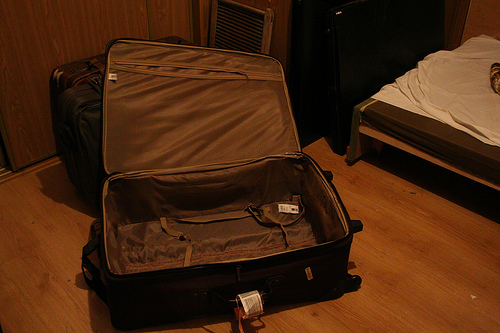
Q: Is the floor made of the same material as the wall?
A: Yes, both the floor and the wall are made of wood.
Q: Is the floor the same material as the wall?
A: Yes, both the floor and the wall are made of wood.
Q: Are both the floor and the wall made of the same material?
A: Yes, both the floor and the wall are made of wood.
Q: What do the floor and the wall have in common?
A: The material, both the floor and the wall are wooden.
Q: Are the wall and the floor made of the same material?
A: Yes, both the wall and the floor are made of wood.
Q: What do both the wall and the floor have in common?
A: The material, both the wall and the floor are wooden.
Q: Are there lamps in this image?
A: No, there are no lamps.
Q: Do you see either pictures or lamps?
A: No, there are no lamps or pictures.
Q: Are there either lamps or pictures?
A: No, there are no lamps or pictures.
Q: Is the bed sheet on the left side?
A: No, the bed sheet is on the right of the image.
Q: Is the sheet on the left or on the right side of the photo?
A: The sheet is on the right of the image.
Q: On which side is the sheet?
A: The sheet is on the right of the image.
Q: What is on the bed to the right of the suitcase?
A: The bed sheet is on the bed.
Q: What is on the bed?
A: The bed sheet is on the bed.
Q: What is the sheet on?
A: The sheet is on the bed.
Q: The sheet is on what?
A: The sheet is on the bed.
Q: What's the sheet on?
A: The sheet is on the bed.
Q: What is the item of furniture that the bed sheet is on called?
A: The piece of furniture is a bed.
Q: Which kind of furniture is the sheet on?
A: The bed sheet is on the bed.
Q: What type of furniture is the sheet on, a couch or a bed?
A: The sheet is on a bed.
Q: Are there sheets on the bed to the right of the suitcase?
A: Yes, there is a sheet on the bed.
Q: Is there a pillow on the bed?
A: No, there is a sheet on the bed.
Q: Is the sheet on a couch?
A: No, the sheet is on a bed.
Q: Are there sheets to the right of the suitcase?
A: Yes, there is a sheet to the right of the suitcase.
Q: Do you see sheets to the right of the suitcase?
A: Yes, there is a sheet to the right of the suitcase.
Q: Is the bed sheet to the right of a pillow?
A: No, the bed sheet is to the right of the suitcase.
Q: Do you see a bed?
A: Yes, there is a bed.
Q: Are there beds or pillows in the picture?
A: Yes, there is a bed.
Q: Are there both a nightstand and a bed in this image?
A: No, there is a bed but no nightstands.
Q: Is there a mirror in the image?
A: No, there are no mirrors.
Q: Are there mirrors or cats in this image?
A: No, there are no mirrors or cats.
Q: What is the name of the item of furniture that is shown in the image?
A: The piece of furniture is a bed.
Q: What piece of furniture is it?
A: The piece of furniture is a bed.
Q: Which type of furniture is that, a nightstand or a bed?
A: That is a bed.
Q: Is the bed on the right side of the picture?
A: Yes, the bed is on the right of the image.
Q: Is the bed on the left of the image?
A: No, the bed is on the right of the image.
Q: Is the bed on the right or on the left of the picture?
A: The bed is on the right of the image.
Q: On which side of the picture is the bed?
A: The bed is on the right of the image.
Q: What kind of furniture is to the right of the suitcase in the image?
A: The piece of furniture is a bed.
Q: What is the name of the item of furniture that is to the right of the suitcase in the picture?
A: The piece of furniture is a bed.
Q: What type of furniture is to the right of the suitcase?
A: The piece of furniture is a bed.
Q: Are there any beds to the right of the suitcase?
A: Yes, there is a bed to the right of the suitcase.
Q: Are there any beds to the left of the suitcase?
A: No, the bed is to the right of the suitcase.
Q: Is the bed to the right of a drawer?
A: No, the bed is to the right of the suitcase.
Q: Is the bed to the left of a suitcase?
A: No, the bed is to the right of a suitcase.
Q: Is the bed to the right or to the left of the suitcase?
A: The bed is to the right of the suitcase.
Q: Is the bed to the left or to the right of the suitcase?
A: The bed is to the right of the suitcase.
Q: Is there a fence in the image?
A: No, there are no fences.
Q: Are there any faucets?
A: No, there are no faucets.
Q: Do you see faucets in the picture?
A: No, there are no faucets.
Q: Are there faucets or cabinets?
A: No, there are no faucets or cabinets.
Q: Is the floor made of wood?
A: Yes, the floor is made of wood.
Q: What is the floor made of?
A: The floor is made of wood.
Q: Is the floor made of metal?
A: No, the floor is made of wood.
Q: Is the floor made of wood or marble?
A: The floor is made of wood.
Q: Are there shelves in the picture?
A: No, there are no shelves.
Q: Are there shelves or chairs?
A: No, there are no shelves or chairs.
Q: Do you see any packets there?
A: No, there are no packets.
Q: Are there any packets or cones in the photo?
A: No, there are no packets or cones.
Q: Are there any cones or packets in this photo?
A: No, there are no packets or cones.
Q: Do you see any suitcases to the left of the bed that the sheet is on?
A: Yes, there is a suitcase to the left of the bed.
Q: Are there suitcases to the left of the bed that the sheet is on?
A: Yes, there is a suitcase to the left of the bed.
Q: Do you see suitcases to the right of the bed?
A: No, the suitcase is to the left of the bed.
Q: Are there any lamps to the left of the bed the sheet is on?
A: No, there is a suitcase to the left of the bed.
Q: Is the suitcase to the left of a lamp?
A: No, the suitcase is to the left of a bed.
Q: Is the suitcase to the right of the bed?
A: No, the suitcase is to the left of the bed.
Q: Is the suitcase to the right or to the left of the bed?
A: The suitcase is to the left of the bed.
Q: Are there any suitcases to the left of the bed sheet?
A: Yes, there is a suitcase to the left of the bed sheet.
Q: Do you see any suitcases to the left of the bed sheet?
A: Yes, there is a suitcase to the left of the bed sheet.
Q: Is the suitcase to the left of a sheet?
A: Yes, the suitcase is to the left of a sheet.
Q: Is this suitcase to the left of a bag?
A: No, the suitcase is to the left of a sheet.